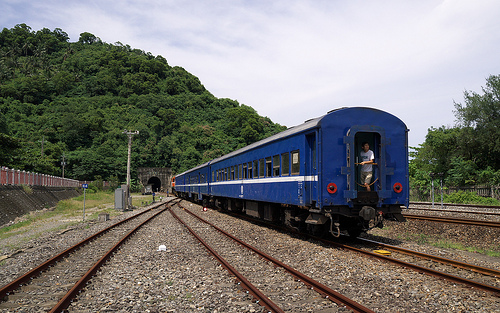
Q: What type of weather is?
A: It is cloudy.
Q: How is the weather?
A: It is cloudy.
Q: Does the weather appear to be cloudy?
A: Yes, it is cloudy.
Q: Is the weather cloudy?
A: Yes, it is cloudy.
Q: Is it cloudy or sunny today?
A: It is cloudy.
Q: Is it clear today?
A: No, it is cloudy.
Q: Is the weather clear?
A: No, it is cloudy.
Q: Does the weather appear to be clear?
A: No, it is cloudy.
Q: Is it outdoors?
A: Yes, it is outdoors.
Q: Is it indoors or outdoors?
A: It is outdoors.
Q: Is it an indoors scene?
A: No, it is outdoors.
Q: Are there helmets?
A: No, there are no helmets.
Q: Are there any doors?
A: Yes, there is a door.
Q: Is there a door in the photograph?
A: Yes, there is a door.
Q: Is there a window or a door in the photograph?
A: Yes, there is a door.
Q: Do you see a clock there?
A: No, there are no clocks.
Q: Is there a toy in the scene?
A: No, there are no toys.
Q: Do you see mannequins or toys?
A: No, there are no toys or mannequins.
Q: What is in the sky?
A: The clouds are in the sky.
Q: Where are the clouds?
A: The clouds are in the sky.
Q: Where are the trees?
A: The trees are on the hill.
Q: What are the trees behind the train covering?
A: The trees are covering the tunnel.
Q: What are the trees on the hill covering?
A: The trees are covering the tunnel.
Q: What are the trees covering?
A: The trees are covering the tunnel.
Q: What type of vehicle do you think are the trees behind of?
A: The trees are behind the train.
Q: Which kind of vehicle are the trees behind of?
A: The trees are behind the train.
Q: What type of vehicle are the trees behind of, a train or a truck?
A: The trees are behind a train.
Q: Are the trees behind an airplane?
A: No, the trees are behind the train.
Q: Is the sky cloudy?
A: Yes, the sky is cloudy.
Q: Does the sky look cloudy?
A: Yes, the sky is cloudy.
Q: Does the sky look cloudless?
A: No, the sky is cloudy.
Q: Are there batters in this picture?
A: No, there are no batters.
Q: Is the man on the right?
A: Yes, the man is on the right of the image.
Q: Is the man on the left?
A: No, the man is on the right of the image.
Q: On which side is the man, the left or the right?
A: The man is on the right of the image.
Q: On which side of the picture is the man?
A: The man is on the right of the image.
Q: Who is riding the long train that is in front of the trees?
A: The man is riding the train.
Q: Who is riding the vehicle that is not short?
A: The man is riding the train.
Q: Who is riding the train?
A: The man is riding the train.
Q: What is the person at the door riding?
A: The man is riding the train.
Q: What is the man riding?
A: The man is riding the train.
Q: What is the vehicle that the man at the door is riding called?
A: The vehicle is a train.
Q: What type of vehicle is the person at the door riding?
A: The man is riding the train.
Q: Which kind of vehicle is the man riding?
A: The man is riding the train.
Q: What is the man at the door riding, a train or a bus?
A: The man is riding a train.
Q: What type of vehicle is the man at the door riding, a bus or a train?
A: The man is riding a train.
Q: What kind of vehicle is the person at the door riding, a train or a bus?
A: The man is riding a train.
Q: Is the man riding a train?
A: Yes, the man is riding a train.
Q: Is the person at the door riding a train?
A: Yes, the man is riding a train.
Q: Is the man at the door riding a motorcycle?
A: No, the man is riding a train.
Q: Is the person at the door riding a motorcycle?
A: No, the man is riding a train.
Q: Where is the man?
A: The man is on the train.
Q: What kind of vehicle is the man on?
A: The man is on the train.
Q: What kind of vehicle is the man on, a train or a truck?
A: The man is on a train.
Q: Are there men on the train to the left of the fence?
A: Yes, there is a man on the train.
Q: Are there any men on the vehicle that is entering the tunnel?
A: Yes, there is a man on the train.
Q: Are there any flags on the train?
A: No, there is a man on the train.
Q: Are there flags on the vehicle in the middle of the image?
A: No, there is a man on the train.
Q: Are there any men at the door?
A: Yes, there is a man at the door.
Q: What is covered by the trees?
A: The tunnel is covered by the trees.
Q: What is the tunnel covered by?
A: The tunnel is covered by the trees.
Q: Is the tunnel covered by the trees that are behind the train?
A: Yes, the tunnel is covered by the trees.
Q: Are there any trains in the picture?
A: Yes, there is a train.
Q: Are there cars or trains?
A: Yes, there is a train.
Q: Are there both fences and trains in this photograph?
A: Yes, there are both a train and a fence.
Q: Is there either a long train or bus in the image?
A: Yes, there is a long train.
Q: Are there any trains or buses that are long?
A: Yes, the train is long.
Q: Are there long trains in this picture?
A: Yes, there is a long train.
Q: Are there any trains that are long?
A: Yes, there is a train that is long.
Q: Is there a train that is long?
A: Yes, there is a train that is long.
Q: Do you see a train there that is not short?
A: Yes, there is a long train.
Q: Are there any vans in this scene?
A: No, there are no vans.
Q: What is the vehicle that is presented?
A: The vehicle is a train.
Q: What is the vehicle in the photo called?
A: The vehicle is a train.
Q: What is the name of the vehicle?
A: The vehicle is a train.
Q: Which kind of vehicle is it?
A: The vehicle is a train.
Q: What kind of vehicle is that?
A: This is a train.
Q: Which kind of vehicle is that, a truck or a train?
A: This is a train.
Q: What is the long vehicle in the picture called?
A: The vehicle is a train.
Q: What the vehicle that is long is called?
A: The vehicle is a train.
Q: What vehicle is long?
A: The vehicle is a train.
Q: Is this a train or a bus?
A: This is a train.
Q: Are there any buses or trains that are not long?
A: No, there is a train but it is long.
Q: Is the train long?
A: Yes, the train is long.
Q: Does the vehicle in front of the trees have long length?
A: Yes, the train is long.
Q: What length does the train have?
A: The train has long length.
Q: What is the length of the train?
A: The train is long.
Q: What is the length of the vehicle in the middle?
A: The train is long.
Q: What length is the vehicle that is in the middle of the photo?
A: The train is long.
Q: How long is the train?
A: The train is long.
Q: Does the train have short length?
A: No, the train is long.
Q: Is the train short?
A: No, the train is long.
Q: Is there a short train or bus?
A: No, there is a train but it is long.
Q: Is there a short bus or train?
A: No, there is a train but it is long.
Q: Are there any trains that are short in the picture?
A: No, there is a train but it is long.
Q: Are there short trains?
A: No, there is a train but it is long.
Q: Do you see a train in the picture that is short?
A: No, there is a train but it is long.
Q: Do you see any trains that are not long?
A: No, there is a train but it is long.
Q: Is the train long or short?
A: The train is long.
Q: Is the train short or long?
A: The train is long.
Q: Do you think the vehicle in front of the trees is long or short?
A: The train is long.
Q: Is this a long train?
A: Yes, this is a long train.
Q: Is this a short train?
A: No, this is a long train.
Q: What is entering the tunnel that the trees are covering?
A: The train is entering the tunnel.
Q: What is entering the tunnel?
A: The train is entering the tunnel.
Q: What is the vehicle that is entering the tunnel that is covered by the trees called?
A: The vehicle is a train.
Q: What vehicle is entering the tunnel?
A: The vehicle is a train.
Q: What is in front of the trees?
A: The train is in front of the trees.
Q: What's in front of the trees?
A: The train is in front of the trees.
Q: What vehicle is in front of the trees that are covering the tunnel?
A: The vehicle is a train.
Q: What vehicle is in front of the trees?
A: The vehicle is a train.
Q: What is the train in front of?
A: The train is in front of the trees.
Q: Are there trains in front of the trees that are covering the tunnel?
A: Yes, there is a train in front of the trees.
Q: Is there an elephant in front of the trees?
A: No, there is a train in front of the trees.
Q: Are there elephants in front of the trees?
A: No, there is a train in front of the trees.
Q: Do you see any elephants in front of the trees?
A: No, there is a train in front of the trees.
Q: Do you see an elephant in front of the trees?
A: No, there is a train in front of the trees.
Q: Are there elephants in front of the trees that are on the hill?
A: No, there is a train in front of the trees.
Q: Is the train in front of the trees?
A: Yes, the train is in front of the trees.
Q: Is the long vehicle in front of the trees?
A: Yes, the train is in front of the trees.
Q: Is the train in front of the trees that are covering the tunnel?
A: Yes, the train is in front of the trees.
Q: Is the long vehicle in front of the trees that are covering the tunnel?
A: Yes, the train is in front of the trees.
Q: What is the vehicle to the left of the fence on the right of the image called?
A: The vehicle is a train.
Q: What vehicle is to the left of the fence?
A: The vehicle is a train.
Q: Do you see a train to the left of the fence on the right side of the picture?
A: Yes, there is a train to the left of the fence.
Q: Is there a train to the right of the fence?
A: No, the train is to the left of the fence.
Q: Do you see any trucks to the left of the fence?
A: No, there is a train to the left of the fence.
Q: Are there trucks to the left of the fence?
A: No, there is a train to the left of the fence.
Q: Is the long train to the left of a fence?
A: Yes, the train is to the left of a fence.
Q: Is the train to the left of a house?
A: No, the train is to the left of a fence.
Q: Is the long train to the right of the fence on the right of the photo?
A: No, the train is to the left of the fence.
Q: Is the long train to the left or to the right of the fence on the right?
A: The train is to the left of the fence.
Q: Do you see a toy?
A: No, there are no toys.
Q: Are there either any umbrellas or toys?
A: No, there are no toys or umbrellas.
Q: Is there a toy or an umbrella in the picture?
A: No, there are no toys or umbrellas.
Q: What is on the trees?
A: The leaves are on the trees.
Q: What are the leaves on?
A: The leaves are on the trees.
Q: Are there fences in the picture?
A: Yes, there is a fence.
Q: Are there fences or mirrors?
A: Yes, there is a fence.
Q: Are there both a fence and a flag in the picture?
A: No, there is a fence but no flags.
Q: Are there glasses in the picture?
A: No, there are no glasses.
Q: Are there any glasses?
A: No, there are no glasses.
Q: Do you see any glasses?
A: No, there are no glasses.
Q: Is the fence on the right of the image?
A: Yes, the fence is on the right of the image.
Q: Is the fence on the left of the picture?
A: No, the fence is on the right of the image.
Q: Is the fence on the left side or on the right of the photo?
A: The fence is on the right of the image.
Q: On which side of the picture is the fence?
A: The fence is on the right of the image.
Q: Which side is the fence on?
A: The fence is on the right of the image.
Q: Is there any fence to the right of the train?
A: Yes, there is a fence to the right of the train.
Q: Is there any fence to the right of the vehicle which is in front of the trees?
A: Yes, there is a fence to the right of the train.